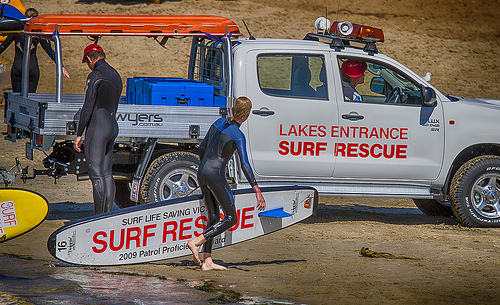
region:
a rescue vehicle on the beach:
[12, 6, 498, 224]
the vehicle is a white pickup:
[10, 8, 497, 225]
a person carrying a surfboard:
[46, 93, 319, 287]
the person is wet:
[190, 87, 265, 274]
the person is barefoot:
[185, 225, 231, 276]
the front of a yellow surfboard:
[0, 179, 55, 249]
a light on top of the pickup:
[310, 6, 390, 45]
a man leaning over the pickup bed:
[70, 40, 122, 212]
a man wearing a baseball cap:
[78, 42, 106, 62]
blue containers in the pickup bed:
[125, 73, 221, 110]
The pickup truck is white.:
[6, 8, 497, 208]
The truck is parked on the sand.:
[11, 1, 497, 237]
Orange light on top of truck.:
[300, 8, 395, 48]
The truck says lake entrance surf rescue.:
[275, 108, 415, 168]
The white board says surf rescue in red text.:
[42, 185, 327, 270]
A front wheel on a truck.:
[446, 143, 497, 228]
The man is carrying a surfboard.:
[47, 92, 322, 277]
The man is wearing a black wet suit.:
[71, 60, 126, 211]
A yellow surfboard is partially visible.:
[0, 182, 51, 242]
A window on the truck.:
[256, 47, 331, 104]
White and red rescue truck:
[0, 1, 496, 227]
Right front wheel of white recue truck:
[448, 147, 496, 228]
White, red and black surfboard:
[45, 178, 316, 268]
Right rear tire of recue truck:
[140, 148, 215, 204]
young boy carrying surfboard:
[195, 91, 266, 269]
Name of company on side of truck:
[272, 111, 422, 162]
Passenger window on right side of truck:
[335, 50, 411, 107]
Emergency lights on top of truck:
[307, 6, 387, 46]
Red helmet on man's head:
[75, 40, 105, 60]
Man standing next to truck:
[71, 39, 122, 214]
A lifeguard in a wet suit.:
[192, 91, 264, 276]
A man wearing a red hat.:
[70, 40, 130, 225]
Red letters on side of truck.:
[273, 121, 411, 163]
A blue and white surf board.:
[35, 184, 330, 271]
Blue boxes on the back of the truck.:
[120, 65, 219, 125]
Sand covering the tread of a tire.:
[446, 141, 498, 228]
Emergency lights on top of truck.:
[300, 13, 390, 57]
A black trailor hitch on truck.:
[18, 166, 62, 184]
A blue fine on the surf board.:
[257, 205, 292, 225]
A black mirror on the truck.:
[419, 83, 441, 106]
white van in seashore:
[10, 27, 497, 225]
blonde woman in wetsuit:
[187, 95, 262, 270]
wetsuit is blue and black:
[186, 115, 257, 266]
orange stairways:
[0, 10, 242, 38]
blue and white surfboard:
[45, 180, 320, 267]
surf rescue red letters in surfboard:
[88, 208, 257, 253]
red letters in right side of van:
[275, 120, 407, 160]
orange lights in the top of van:
[317, 13, 383, 49]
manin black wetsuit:
[70, 37, 122, 220]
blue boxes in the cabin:
[125, 67, 216, 109]